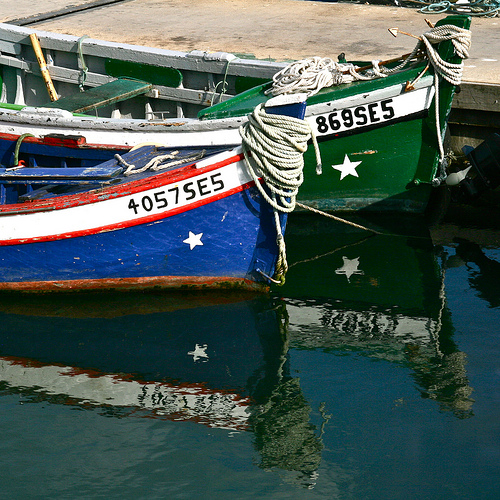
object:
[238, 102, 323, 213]
rope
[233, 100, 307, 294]
stern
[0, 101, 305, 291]
boat